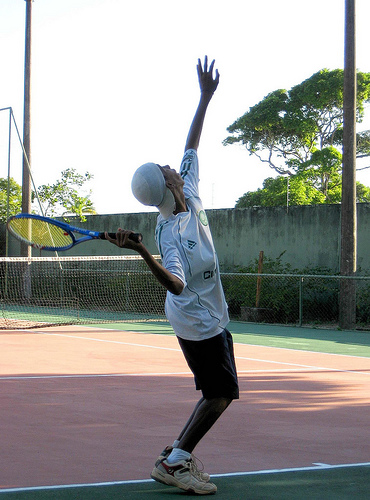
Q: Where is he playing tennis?
A: Tennis court.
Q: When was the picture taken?
A: Day time.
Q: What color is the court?
A: Brown and green.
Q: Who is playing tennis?
A: A man.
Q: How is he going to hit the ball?
A: With the racquet.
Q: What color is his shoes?
A: White.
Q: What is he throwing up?
A: Tennis ball.